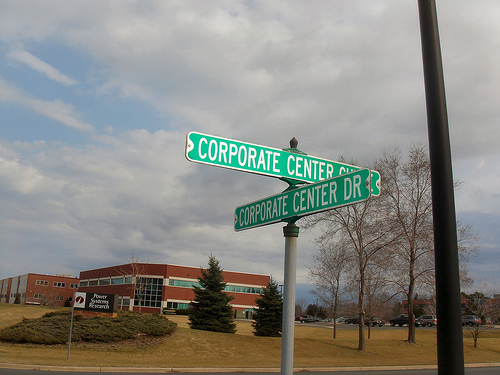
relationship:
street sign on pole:
[232, 167, 381, 232] [283, 135, 302, 373]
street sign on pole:
[181, 131, 383, 196] [283, 135, 302, 373]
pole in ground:
[391, 32, 485, 182] [183, 327, 258, 365]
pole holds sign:
[69, 293, 74, 365] [186, 127, 386, 227]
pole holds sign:
[281, 129, 301, 374] [70, 295, 75, 306]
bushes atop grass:
[0, 290, 181, 345] [63, 317, 280, 365]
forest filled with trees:
[326, 175, 396, 361] [301, 148, 432, 365]